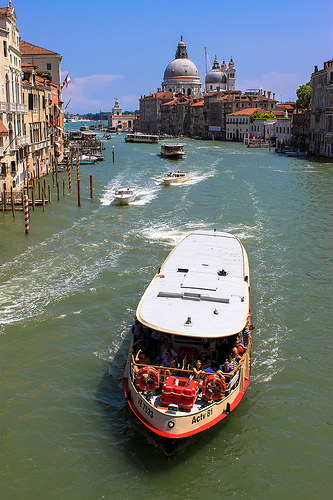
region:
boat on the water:
[121, 208, 296, 433]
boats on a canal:
[75, 111, 317, 466]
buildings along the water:
[103, 22, 330, 188]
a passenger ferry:
[101, 198, 292, 439]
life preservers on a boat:
[130, 357, 252, 410]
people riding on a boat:
[119, 325, 251, 431]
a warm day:
[17, 4, 320, 439]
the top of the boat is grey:
[114, 201, 285, 423]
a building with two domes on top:
[131, 24, 283, 139]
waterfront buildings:
[1, 3, 100, 231]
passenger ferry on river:
[110, 209, 263, 451]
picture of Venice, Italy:
[20, 19, 323, 468]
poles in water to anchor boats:
[12, 152, 98, 237]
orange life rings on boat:
[197, 368, 232, 405]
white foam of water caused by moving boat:
[139, 219, 171, 246]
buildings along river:
[135, 38, 330, 144]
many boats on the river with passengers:
[92, 112, 197, 214]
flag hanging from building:
[54, 70, 82, 97]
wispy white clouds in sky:
[70, 69, 128, 103]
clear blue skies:
[89, 12, 278, 59]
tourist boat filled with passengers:
[122, 229, 250, 440]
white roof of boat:
[135, 229, 250, 335]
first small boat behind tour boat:
[114, 183, 137, 205]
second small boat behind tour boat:
[162, 169, 187, 187]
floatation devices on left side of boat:
[201, 374, 225, 401]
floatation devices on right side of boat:
[136, 366, 158, 393]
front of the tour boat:
[127, 366, 240, 448]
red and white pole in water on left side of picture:
[21, 191, 32, 236]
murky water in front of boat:
[1, 444, 331, 499]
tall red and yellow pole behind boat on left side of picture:
[75, 154, 82, 205]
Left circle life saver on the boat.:
[136, 365, 159, 395]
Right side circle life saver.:
[202, 369, 227, 399]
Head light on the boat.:
[167, 419, 175, 429]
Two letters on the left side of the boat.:
[133, 395, 144, 411]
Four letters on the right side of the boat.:
[189, 411, 207, 422]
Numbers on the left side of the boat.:
[142, 402, 155, 418]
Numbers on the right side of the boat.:
[206, 408, 214, 417]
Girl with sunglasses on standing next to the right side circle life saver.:
[193, 359, 204, 376]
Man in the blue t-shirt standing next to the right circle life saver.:
[220, 360, 232, 377]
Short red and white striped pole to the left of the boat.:
[18, 193, 35, 238]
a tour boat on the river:
[112, 212, 245, 445]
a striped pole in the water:
[15, 192, 40, 234]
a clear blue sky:
[78, 27, 114, 67]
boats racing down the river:
[109, 159, 192, 220]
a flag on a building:
[62, 72, 80, 91]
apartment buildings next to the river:
[7, 14, 59, 181]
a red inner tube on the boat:
[135, 365, 161, 398]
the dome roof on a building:
[159, 57, 204, 79]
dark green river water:
[242, 432, 330, 494]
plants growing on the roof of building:
[253, 107, 273, 121]